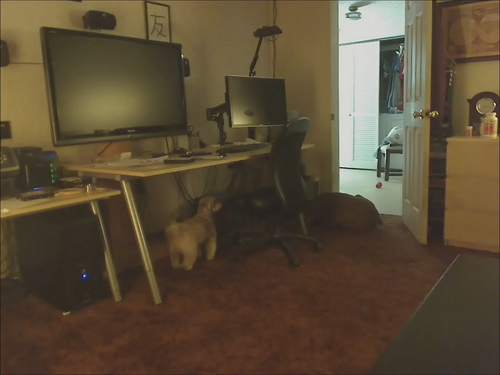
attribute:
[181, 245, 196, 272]
leg — white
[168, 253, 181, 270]
leg — white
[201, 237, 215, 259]
leg — white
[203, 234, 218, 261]
leg — white 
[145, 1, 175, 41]
symbol — framed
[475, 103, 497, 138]
bottle — white 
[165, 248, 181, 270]
leg — white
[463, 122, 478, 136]
bottle — white 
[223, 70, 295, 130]
numeral — black, roman